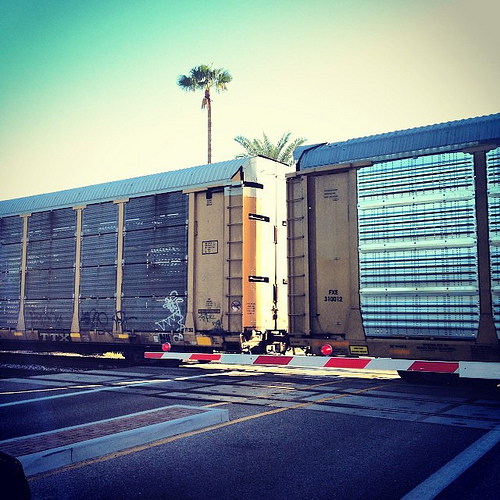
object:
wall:
[310, 173, 358, 337]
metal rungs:
[286, 174, 305, 316]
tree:
[178, 63, 233, 164]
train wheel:
[122, 349, 157, 363]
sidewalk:
[30, 368, 500, 428]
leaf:
[234, 136, 256, 156]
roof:
[0, 155, 254, 215]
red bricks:
[0, 404, 212, 459]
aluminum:
[0, 155, 257, 213]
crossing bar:
[144, 351, 500, 380]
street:
[0, 365, 499, 500]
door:
[193, 194, 224, 331]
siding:
[487, 149, 500, 341]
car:
[286, 110, 499, 348]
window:
[248, 213, 269, 222]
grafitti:
[80, 309, 137, 338]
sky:
[0, 0, 499, 199]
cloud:
[0, 0, 498, 206]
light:
[321, 344, 332, 355]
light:
[161, 342, 170, 351]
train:
[0, 111, 500, 383]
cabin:
[0, 154, 286, 351]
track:
[0, 352, 500, 401]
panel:
[358, 151, 483, 342]